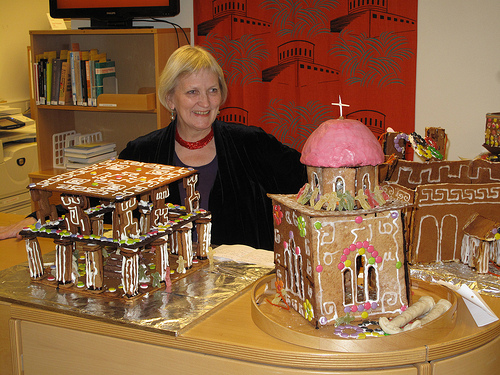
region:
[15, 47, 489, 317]
a woman behind three ginger bread houses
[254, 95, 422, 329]
a temple made from ginger bread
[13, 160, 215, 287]
a structure made from ginger bread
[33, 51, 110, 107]
books on a shelf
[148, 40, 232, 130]
a woman with blonde hair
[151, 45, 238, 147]
a woman wearing a red choker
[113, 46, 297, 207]
a woman wearing a black jacket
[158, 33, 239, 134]
a woman who is smiling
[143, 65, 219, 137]
a woman wearing an earring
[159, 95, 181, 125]
an erring on an ear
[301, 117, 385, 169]
the top of a gingerbread house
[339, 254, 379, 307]
arched windows on a gingerbread house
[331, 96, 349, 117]
a white cross on top of a gingerbread house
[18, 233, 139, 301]
collumns on a gingerbread house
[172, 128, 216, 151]
a red shiny necklace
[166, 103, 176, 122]
earring in a left ear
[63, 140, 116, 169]
books stacked on a shelf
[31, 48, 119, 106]
books standing on a shelf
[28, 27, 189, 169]
a brown bookshelf with books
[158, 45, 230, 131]
a woman with blonde hair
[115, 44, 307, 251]
smiling blonde woman in black and purple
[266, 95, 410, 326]
gingerbread cathedral with pink dome and white cross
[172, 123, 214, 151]
shiny red beaded necklace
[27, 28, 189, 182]
tan wooden bookshelf with assorted books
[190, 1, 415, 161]
red tapestry with black and green pattern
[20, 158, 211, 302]
gingerbread structure with white frosting accents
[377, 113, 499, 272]
gingerbread structure with white frosting accents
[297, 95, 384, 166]
pink frosting dome with white cross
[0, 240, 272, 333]
plywood covered in shiny foil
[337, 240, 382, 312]
gingerbread window cutouts with pink and purple accent candies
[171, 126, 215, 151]
a red necklace on a woman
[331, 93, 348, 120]
a white cross on top of a cake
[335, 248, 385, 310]
arched windows on a cake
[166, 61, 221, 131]
a woman's face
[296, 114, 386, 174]
a dome on top of a cake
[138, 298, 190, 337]
silver platter under cake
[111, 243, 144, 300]
pillars holding up cake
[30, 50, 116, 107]
books on a book shelf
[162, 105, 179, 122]
a woman's earring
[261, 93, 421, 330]
a gingerbread house sculpture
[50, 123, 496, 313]
The ginger bread houses are on the table.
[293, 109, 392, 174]
The dome is pink.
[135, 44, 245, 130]
The woman is smiling.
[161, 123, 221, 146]
The necklace is red.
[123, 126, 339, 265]
The jacket is black.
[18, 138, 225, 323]
The frosting is white.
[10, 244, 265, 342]
The plate is silver.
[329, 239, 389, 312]
The windows are arched.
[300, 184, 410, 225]
Gummies are on the house.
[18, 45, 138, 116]
The books are on the shelf.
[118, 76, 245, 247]
A woman in black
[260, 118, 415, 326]
a house made outof cookie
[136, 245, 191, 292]
toy people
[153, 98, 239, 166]
A woman with a red necklace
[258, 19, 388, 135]
Red black and green curtain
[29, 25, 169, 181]
Books on the shelf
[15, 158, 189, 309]
A house made out of cookie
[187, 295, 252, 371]
A Brown table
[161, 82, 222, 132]
A lady with earrings on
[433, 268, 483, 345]
A piece of white paper on a desk